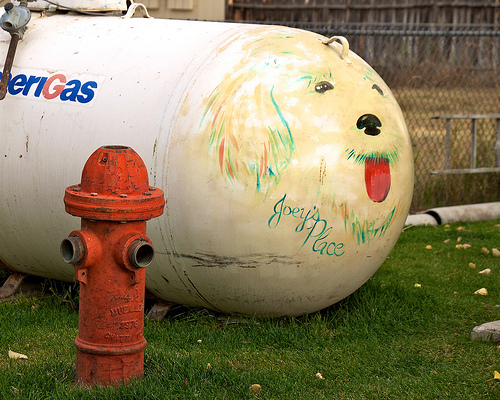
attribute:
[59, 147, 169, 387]
fire hydrant — red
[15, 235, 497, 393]
grass — green, overgrown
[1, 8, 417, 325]
gas tank — large, white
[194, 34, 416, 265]
drawing — dog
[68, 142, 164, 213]
cap — red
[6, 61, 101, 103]
logo — red, blue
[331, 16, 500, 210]
fence — gray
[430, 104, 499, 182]
ladder — aluminum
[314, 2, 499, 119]
wooden fence — brown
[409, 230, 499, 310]
leaves — yellow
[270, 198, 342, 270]
writing — green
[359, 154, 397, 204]
tongue — red